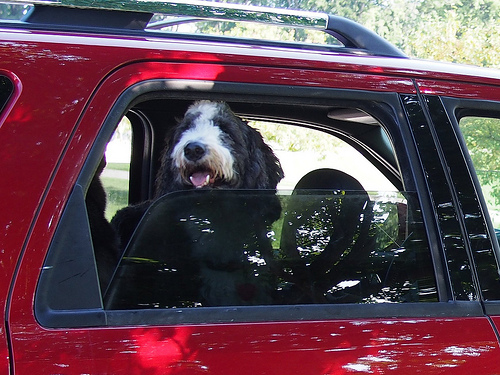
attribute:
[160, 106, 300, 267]
dog — white, black, long haired, medium sized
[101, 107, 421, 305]
window — open, partially dwn, half down, rolled down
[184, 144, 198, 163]
nose — dark, wet, black, shiny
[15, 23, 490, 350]
car — red, large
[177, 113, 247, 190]
head — white, black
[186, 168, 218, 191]
mouth — open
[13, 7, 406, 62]
rack — shiny, black, silver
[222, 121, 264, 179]
fur — black, white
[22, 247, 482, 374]
door — red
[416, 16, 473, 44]
leaves — green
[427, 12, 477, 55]
vegetation — green